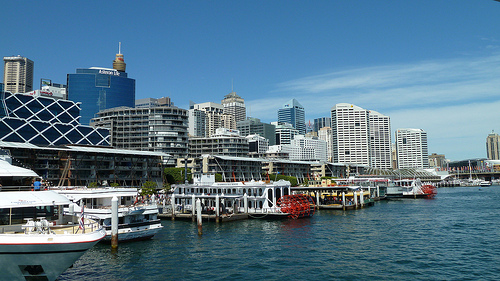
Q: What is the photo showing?
A: It is showing a city.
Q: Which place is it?
A: It is a city.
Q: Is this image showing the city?
A: Yes, it is showing the city.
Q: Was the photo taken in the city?
A: Yes, it was taken in the city.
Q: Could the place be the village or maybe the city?
A: It is the city.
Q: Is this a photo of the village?
A: No, the picture is showing the city.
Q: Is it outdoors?
A: Yes, it is outdoors.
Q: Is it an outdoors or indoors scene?
A: It is outdoors.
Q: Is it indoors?
A: No, it is outdoors.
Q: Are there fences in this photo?
A: No, there are no fences.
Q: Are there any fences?
A: No, there are no fences.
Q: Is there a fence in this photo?
A: No, there are no fences.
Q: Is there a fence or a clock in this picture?
A: No, there are no fences or clocks.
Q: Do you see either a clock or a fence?
A: No, there are no fences or clocks.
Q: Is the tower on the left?
A: Yes, the tower is on the left of the image.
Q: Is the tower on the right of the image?
A: No, the tower is on the left of the image.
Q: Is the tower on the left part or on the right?
A: The tower is on the left of the image.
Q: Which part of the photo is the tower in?
A: The tower is on the left of the image.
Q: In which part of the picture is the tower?
A: The tower is on the left of the image.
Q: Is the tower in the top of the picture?
A: Yes, the tower is in the top of the image.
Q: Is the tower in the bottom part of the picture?
A: No, the tower is in the top of the image.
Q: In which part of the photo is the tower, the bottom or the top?
A: The tower is in the top of the image.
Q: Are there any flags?
A: Yes, there is a flag.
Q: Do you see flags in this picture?
A: Yes, there is a flag.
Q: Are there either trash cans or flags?
A: Yes, there is a flag.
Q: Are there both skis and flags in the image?
A: No, there is a flag but no skis.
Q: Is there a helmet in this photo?
A: No, there are no helmets.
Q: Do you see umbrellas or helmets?
A: No, there are no helmets or umbrellas.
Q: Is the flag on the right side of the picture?
A: Yes, the flag is on the right of the image.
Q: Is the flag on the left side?
A: No, the flag is on the right of the image.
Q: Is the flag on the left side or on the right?
A: The flag is on the right of the image.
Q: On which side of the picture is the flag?
A: The flag is on the right of the image.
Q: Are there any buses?
A: No, there are no buses.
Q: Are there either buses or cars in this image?
A: No, there are no buses or cars.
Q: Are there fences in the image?
A: No, there are no fences.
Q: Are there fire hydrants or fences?
A: No, there are no fences or fire hydrants.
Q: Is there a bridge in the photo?
A: No, there are no bridges.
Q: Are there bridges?
A: No, there are no bridges.